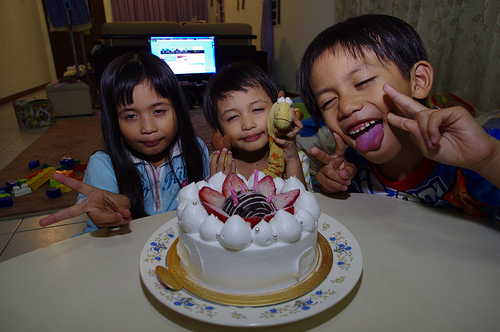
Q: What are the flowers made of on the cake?
A: Icing.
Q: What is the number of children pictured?
A: 3.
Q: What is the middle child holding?
A: Stuffed giraffe.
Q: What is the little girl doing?
A: Showing the peace sign.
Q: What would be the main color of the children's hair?
A: Black.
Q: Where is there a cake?
A: On table.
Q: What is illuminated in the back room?
A: Television.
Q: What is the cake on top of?
A: Plate.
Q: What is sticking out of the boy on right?
A: Tongue.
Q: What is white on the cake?
A: Icing.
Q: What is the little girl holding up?
A: Two fingers.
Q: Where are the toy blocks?
A: On floor.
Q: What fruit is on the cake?
A: Strawberry.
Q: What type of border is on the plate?
A: Blue floral.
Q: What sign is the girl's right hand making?
A: Peace sign.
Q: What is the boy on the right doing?
A: Poking out his tongue.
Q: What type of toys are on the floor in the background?
A: Mega bloks.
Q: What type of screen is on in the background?
A: Television.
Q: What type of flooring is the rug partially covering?
A: Ceramic tile.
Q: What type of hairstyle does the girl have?
A: Long with bangs.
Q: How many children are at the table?
A: Three.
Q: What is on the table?
A: Cake.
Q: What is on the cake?
A: A flower.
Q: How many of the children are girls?
A: One.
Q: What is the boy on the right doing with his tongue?
A: Sticking it out.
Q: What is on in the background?
A: Television.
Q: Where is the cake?
A: On the table.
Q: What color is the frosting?
A: White.